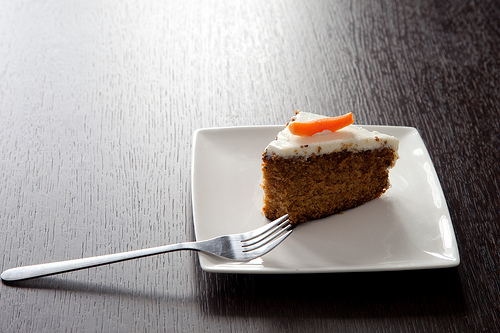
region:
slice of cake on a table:
[186, 108, 461, 280]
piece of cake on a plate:
[188, 108, 463, 275]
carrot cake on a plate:
[188, 109, 463, 276]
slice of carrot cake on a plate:
[186, 107, 463, 272]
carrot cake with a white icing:
[260, 109, 402, 231]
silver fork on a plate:
[0, 212, 304, 295]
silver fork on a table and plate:
[0, 212, 297, 293]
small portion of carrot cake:
[258, 108, 402, 231]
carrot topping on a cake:
[283, 113, 361, 135]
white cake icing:
[266, 110, 402, 157]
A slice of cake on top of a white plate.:
[190, 123, 456, 270]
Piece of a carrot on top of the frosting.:
[285, 110, 355, 135]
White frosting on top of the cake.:
[260, 110, 400, 156]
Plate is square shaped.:
[187, 120, 457, 266]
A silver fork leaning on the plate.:
[0, 213, 290, 281]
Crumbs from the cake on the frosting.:
[270, 132, 387, 156]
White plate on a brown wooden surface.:
[2, 47, 497, 329]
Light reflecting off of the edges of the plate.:
[201, 138, 456, 269]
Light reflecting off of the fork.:
[0, 212, 291, 279]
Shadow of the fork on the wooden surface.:
[2, 278, 208, 304]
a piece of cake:
[169, 90, 429, 303]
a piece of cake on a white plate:
[178, 70, 465, 304]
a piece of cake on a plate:
[213, 78, 472, 280]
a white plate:
[185, 91, 447, 300]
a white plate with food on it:
[171, 104, 491, 275]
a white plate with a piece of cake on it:
[173, 98, 486, 304]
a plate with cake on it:
[176, 89, 426, 304]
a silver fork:
[15, 223, 316, 288]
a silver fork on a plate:
[56, 83, 431, 304]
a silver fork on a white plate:
[51, 98, 456, 309]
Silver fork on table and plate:
[3, 208, 323, 287]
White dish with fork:
[177, 63, 474, 310]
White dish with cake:
[180, 75, 470, 292]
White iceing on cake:
[267, 100, 395, 162]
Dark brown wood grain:
[7, 285, 64, 331]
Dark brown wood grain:
[78, 285, 123, 330]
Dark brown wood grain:
[165, 283, 205, 328]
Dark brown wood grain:
[77, 54, 143, 116]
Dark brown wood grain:
[43, 118, 206, 216]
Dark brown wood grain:
[340, 28, 452, 79]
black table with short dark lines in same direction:
[3, 11, 481, 317]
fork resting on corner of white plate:
[0, 206, 296, 287]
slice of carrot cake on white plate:
[186, 116, 461, 276]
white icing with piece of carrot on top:
[260, 96, 395, 226]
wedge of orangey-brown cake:
[260, 106, 395, 226]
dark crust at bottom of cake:
[262, 190, 392, 225]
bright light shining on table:
[111, 10, 256, 310]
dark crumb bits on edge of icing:
[260, 105, 397, 160]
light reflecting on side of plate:
[410, 140, 455, 255]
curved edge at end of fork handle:
[0, 247, 60, 292]